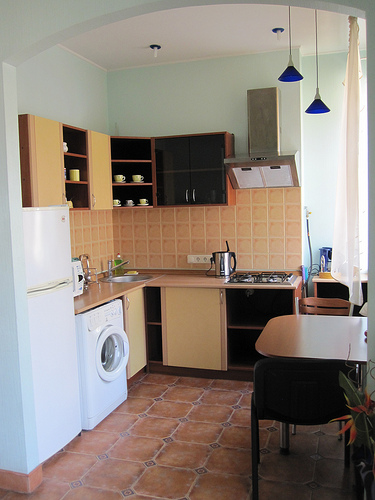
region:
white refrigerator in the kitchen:
[13, 201, 90, 472]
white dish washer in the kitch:
[72, 300, 150, 438]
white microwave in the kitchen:
[61, 260, 90, 300]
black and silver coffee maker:
[201, 239, 242, 278]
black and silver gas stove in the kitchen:
[228, 262, 297, 289]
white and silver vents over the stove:
[219, 84, 306, 194]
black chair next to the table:
[244, 355, 355, 496]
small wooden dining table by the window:
[249, 309, 370, 373]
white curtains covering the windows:
[321, 13, 366, 309]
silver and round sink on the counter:
[97, 254, 157, 291]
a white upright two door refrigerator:
[19, 204, 83, 465]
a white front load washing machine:
[72, 297, 129, 433]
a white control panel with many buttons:
[84, 299, 123, 332]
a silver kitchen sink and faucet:
[99, 257, 154, 283]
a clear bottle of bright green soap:
[111, 252, 123, 277]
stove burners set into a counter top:
[223, 269, 300, 288]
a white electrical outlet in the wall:
[186, 253, 220, 263]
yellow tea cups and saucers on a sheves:
[111, 171, 151, 207]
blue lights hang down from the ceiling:
[275, 26, 330, 116]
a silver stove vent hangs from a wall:
[221, 85, 302, 189]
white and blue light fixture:
[275, 5, 302, 83]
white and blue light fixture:
[301, 0, 327, 115]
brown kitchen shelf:
[20, 109, 65, 207]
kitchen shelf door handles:
[182, 186, 197, 205]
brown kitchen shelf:
[84, 126, 105, 204]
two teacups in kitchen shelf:
[110, 170, 140, 178]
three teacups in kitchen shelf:
[105, 195, 143, 210]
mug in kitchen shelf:
[66, 161, 76, 177]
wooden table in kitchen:
[250, 309, 365, 361]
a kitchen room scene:
[7, 49, 365, 492]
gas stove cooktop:
[233, 266, 291, 286]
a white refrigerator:
[24, 206, 81, 451]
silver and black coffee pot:
[208, 242, 237, 280]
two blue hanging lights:
[276, 12, 338, 122]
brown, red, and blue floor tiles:
[86, 431, 232, 494]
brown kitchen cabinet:
[158, 284, 231, 370]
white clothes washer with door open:
[76, 305, 129, 417]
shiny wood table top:
[255, 304, 367, 366]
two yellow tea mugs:
[112, 170, 150, 186]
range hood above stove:
[226, 86, 307, 196]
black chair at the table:
[234, 346, 363, 499]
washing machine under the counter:
[74, 298, 129, 430]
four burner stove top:
[224, 266, 296, 291]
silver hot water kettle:
[201, 236, 239, 279]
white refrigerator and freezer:
[16, 201, 85, 458]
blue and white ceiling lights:
[266, 5, 336, 125]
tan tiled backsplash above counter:
[66, 186, 307, 272]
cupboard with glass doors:
[148, 130, 234, 208]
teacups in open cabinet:
[107, 133, 161, 214]